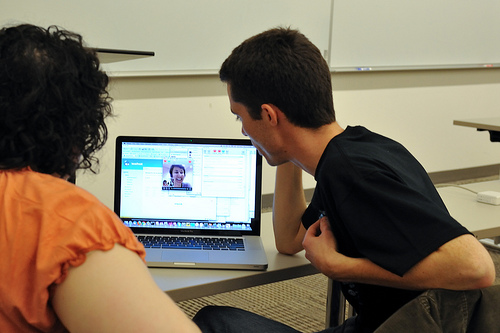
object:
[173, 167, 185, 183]
face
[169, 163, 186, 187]
boy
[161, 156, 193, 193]
picture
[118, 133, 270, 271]
computer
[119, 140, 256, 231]
screen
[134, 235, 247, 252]
keyboard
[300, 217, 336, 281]
hand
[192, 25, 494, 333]
person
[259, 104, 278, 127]
ear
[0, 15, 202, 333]
girl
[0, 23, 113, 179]
hair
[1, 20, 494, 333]
two people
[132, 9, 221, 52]
part of a white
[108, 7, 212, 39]
board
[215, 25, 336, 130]
man's short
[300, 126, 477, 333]
shirt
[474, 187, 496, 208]
white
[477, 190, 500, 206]
mouse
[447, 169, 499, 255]
part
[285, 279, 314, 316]
portion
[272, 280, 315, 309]
carpet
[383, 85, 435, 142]
wall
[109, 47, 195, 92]
blue and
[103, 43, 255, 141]
marker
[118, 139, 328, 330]
deck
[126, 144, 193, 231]
skype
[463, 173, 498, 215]
table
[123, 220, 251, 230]
tabs open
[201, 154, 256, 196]
text box open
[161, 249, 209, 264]
silver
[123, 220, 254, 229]
multiple icons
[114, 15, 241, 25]
dry erase board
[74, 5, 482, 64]
background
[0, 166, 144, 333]
orange shirt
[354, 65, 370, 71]
blue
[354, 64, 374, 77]
market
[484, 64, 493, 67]
orange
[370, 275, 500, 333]
of chair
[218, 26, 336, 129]
black hair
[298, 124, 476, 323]
man wears a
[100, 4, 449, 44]
large